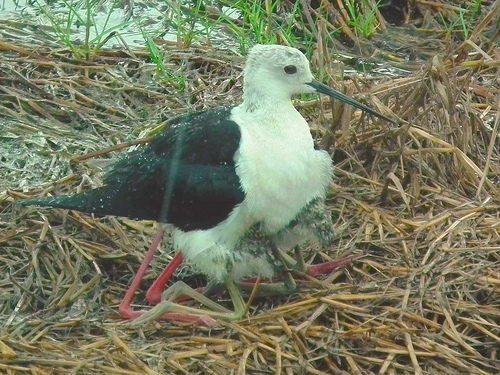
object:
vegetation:
[381, 151, 497, 368]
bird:
[14, 43, 396, 319]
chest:
[239, 106, 334, 217]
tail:
[13, 172, 148, 220]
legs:
[108, 222, 358, 328]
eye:
[283, 64, 297, 75]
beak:
[300, 78, 404, 129]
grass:
[54, 2, 298, 61]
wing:
[100, 107, 235, 195]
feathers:
[246, 83, 333, 216]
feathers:
[149, 102, 250, 216]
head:
[239, 43, 310, 98]